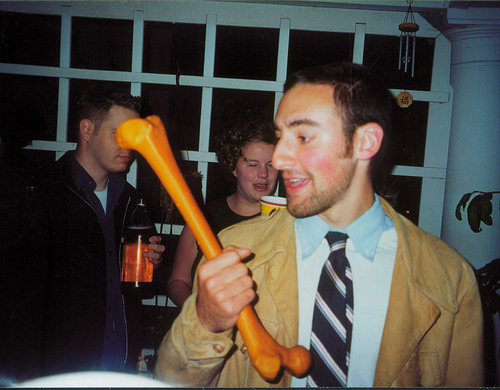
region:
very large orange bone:
[110, 105, 306, 380]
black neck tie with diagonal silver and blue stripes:
[303, 226, 358, 388]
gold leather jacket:
[162, 203, 485, 388]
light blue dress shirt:
[288, 205, 402, 387]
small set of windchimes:
[387, 4, 429, 116]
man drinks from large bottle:
[69, 88, 179, 306]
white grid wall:
[4, 6, 437, 226]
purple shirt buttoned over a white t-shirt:
[62, 147, 134, 373]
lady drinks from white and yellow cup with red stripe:
[211, 124, 294, 226]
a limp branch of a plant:
[452, 148, 499, 250]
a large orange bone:
[115, 112, 312, 381]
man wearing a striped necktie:
[303, 230, 358, 388]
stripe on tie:
[316, 292, 348, 340]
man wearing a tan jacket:
[153, 195, 487, 387]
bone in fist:
[117, 112, 321, 379]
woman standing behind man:
[163, 119, 280, 308]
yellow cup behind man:
[258, 194, 284, 217]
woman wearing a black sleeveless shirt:
[198, 195, 264, 244]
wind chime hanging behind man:
[392, 3, 424, 110]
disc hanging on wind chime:
[395, 90, 415, 110]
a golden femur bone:
[112, 109, 316, 383]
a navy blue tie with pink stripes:
[297, 221, 359, 388]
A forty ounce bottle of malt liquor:
[118, 190, 166, 304]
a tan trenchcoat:
[150, 190, 484, 386]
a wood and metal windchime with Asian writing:
[393, 0, 421, 111]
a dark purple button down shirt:
[67, 150, 132, 377]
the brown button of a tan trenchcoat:
[206, 341, 225, 356]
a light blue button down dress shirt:
[280, 190, 400, 388]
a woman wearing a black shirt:
[164, 106, 281, 320]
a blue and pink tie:
[297, 225, 355, 389]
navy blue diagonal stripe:
[316, 265, 351, 325]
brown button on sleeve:
[211, 343, 226, 354]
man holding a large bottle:
[8, 95, 163, 374]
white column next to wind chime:
[438, 7, 498, 271]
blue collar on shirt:
[291, 192, 391, 262]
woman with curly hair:
[216, 119, 282, 176]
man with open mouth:
[283, 174, 310, 191]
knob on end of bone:
[288, 345, 310, 376]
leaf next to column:
[454, 187, 499, 230]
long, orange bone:
[115, 110, 309, 382]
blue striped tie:
[305, 231, 367, 388]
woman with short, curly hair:
[212, 112, 281, 202]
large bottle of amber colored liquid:
[118, 192, 156, 299]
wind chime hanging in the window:
[397, 0, 417, 110]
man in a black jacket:
[20, 82, 135, 369]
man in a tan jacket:
[173, 65, 479, 387]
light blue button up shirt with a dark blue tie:
[288, 202, 392, 387]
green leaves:
[451, 189, 498, 235]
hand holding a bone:
[193, 244, 256, 324]